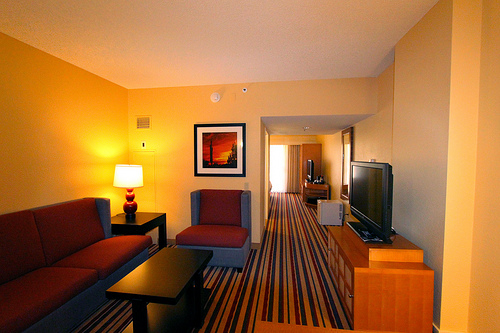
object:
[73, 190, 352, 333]
flooring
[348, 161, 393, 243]
television set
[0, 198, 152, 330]
sofa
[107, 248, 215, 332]
coffee table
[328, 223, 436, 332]
dresser drawer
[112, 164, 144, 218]
lamp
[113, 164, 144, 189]
lampshade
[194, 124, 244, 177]
catus photograph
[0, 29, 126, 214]
wall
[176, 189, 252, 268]
chair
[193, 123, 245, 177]
frame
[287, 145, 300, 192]
curtain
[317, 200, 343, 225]
fridge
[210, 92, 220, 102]
smoke detector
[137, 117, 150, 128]
air vent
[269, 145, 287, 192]
window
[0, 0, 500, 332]
hotel room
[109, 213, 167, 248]
side table